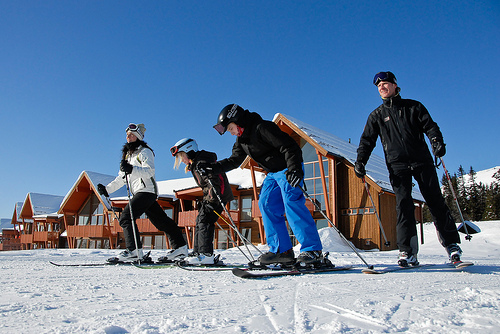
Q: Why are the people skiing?
A: Enjoyment.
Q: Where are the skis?
A: On the people.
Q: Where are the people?
A: At a ski lodge.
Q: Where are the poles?
A: In the people's hands.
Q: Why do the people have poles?
A: For speed and balance.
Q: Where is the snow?
A: On the ground.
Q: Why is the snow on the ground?
A: It is cold.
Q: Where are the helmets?
A: On the peoples heads.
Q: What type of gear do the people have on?
A: Ski gear.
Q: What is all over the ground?
A: Snow.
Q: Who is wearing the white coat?
A: The person on the left.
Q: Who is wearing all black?
A: The man on the right.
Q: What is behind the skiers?
A: Buildings.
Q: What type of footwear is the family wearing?
A: Ski boots.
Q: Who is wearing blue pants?
A: The skier second from the right.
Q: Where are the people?
A: Ski slope.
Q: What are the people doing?
A: Standing.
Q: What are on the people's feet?
A: Skis.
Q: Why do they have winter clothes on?
A: It is cold.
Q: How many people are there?
A: Four.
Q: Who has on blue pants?
A: The person in front.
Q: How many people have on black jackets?
A: Three.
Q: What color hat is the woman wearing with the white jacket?
A: White.